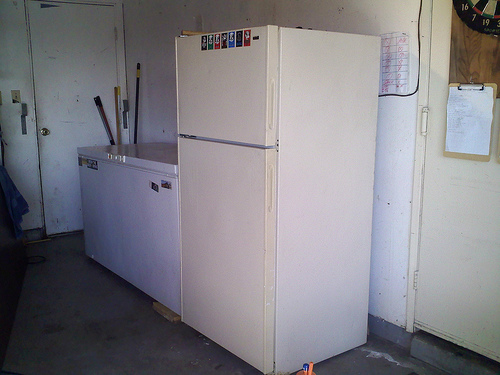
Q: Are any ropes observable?
A: No, there are no ropes.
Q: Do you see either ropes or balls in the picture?
A: No, there are no ropes or balls.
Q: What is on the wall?
A: The paper is on the wall.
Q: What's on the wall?
A: The paper is on the wall.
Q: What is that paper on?
A: The paper is on the wall.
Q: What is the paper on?
A: The paper is on the wall.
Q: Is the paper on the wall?
A: Yes, the paper is on the wall.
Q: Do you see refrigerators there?
A: Yes, there is a refrigerator.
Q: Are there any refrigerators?
A: Yes, there is a refrigerator.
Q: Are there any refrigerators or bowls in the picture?
A: Yes, there is a refrigerator.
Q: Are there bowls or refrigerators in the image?
A: Yes, there is a refrigerator.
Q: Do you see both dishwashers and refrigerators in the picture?
A: No, there is a refrigerator but no dishwashers.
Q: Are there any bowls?
A: No, there are no bowls.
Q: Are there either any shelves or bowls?
A: No, there are no bowls or shelves.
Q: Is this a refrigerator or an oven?
A: This is a refrigerator.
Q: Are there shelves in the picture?
A: No, there are no shelves.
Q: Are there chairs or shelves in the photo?
A: No, there are no shelves or chairs.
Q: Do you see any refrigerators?
A: Yes, there is a refrigerator.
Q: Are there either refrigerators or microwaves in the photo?
A: Yes, there is a refrigerator.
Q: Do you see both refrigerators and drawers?
A: No, there is a refrigerator but no drawers.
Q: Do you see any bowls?
A: No, there are no bowls.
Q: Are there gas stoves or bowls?
A: No, there are no bowls or gas stoves.